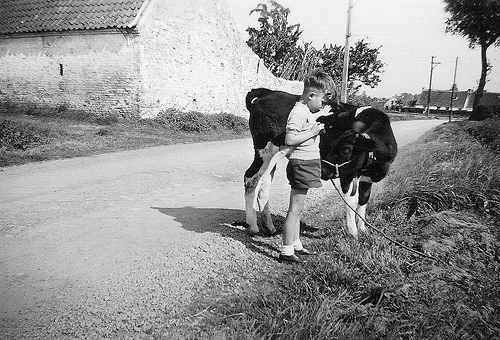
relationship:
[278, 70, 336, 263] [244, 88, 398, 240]
boy standing next to calf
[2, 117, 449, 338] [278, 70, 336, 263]
road near boy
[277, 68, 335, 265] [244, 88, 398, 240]
boy petting a calf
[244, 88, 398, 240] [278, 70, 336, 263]
calf sniffing boy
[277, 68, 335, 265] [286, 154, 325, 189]
boy wearing shorts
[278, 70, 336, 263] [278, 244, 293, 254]
boy wearing sock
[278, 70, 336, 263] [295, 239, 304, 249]
boy wearing sock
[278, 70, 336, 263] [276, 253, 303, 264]
boy wearing shoe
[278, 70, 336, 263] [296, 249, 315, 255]
boy wearing shoe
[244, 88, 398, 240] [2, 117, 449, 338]
calf on road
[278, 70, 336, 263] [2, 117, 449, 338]
boy on road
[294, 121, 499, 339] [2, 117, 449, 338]
vegetation near road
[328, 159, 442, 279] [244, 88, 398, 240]
rope around calf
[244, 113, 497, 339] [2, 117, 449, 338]
vegetation near road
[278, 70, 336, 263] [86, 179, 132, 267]
boy in road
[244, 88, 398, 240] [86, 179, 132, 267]
calf in road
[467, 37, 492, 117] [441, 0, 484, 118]
branch of tree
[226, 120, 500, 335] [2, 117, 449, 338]
grass on road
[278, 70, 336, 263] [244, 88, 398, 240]
boy petting calf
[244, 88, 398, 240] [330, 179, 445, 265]
calf on rope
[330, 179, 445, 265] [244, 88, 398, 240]
rope on calf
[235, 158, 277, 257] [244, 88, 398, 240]
legs of calf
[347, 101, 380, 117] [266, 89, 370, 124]
patch on back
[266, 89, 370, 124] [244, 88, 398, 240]
back on calf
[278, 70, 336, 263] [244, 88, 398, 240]
boy with calf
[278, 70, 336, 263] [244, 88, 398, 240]
boy next to calf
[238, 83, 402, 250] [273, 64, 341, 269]
calf next to boy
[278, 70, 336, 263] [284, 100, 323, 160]
boy wearing shirt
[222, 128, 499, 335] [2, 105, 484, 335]
grass growing on ground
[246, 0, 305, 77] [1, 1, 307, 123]
tree standing in front of house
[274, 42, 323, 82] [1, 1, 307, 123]
tree standing in front of house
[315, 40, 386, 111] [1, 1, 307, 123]
tree standing in front of house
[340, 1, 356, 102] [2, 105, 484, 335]
pole standing in ground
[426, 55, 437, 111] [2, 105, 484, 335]
pole standing in ground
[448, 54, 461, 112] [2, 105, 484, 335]
pole standing in ground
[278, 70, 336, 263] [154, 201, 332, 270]
boy has shadow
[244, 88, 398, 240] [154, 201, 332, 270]
calf has shadow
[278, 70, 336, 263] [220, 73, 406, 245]
boy petting cow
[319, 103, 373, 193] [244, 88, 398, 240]
face on calf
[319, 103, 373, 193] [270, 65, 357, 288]
face near boy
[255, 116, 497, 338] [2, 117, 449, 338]
grassy vegetation near road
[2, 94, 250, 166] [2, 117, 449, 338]
grassy vegetation near road